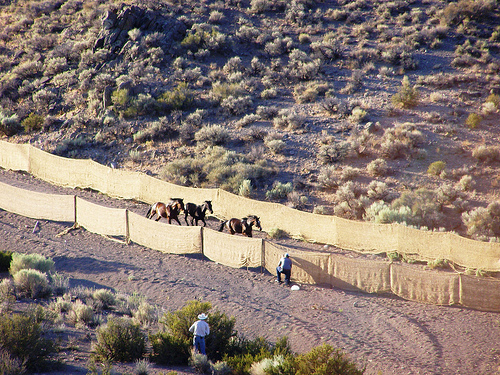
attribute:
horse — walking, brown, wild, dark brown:
[220, 213, 263, 239]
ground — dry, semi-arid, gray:
[2, 0, 499, 372]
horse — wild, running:
[183, 199, 216, 227]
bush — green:
[145, 328, 193, 369]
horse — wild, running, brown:
[142, 198, 187, 225]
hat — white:
[195, 312, 209, 321]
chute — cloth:
[2, 138, 499, 316]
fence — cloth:
[0, 182, 499, 314]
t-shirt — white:
[276, 254, 292, 273]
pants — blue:
[191, 334, 205, 359]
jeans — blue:
[191, 336, 207, 359]